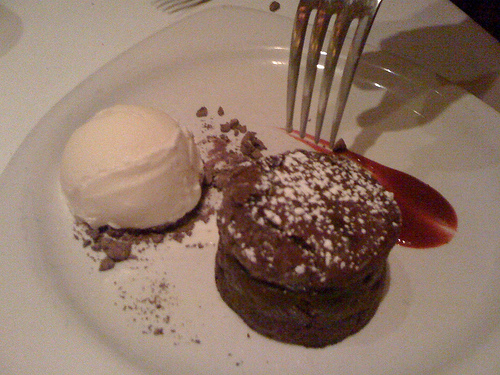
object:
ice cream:
[57, 102, 202, 233]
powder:
[291, 262, 307, 277]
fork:
[284, 0, 379, 149]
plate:
[0, 7, 499, 374]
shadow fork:
[151, 0, 211, 20]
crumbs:
[194, 105, 210, 119]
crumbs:
[245, 332, 253, 340]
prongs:
[327, 20, 376, 154]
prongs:
[313, 12, 351, 145]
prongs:
[300, 10, 329, 141]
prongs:
[284, 9, 310, 134]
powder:
[213, 106, 225, 118]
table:
[0, 0, 499, 174]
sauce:
[275, 128, 457, 250]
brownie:
[210, 146, 405, 353]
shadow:
[349, 20, 499, 131]